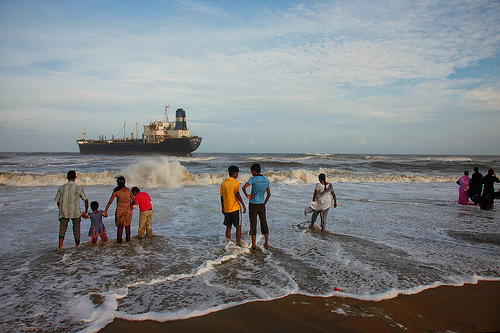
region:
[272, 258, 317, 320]
edge of a shore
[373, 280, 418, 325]
part of a shore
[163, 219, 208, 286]
part of a water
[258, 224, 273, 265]
part of a leg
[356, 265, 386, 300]
edge of a shore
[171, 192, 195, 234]
part fo a water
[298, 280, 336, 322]
edge of a shore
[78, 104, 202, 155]
a ship near the coast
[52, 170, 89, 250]
a person on the beach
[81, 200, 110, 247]
a child on the beach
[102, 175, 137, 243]
a person on the beach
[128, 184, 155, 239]
a person wearing red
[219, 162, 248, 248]
a person wearing a yellow shirt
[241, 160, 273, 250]
a person wearing a blue shirt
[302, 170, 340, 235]
a person standing in the water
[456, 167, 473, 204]
a person standing in the water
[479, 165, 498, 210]
a person standing in the water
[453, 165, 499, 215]
The people are standing in water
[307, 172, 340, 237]
The woman is wearing a white shirt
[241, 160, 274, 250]
The guy is wearing a blue shirt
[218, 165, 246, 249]
The person is wearing a yellow shirt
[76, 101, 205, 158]
A large ship is in the ocean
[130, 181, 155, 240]
The child is looking down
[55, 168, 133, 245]
The adults are holding the childs arms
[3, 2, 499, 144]
Cloud covered sky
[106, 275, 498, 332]
The sand on the beach is wet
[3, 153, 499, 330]
The ocean is wavy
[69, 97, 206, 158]
A tanker on the surf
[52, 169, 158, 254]
A family watching the tanker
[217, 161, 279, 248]
Two friends watching the tanker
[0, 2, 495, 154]
A very overcast sky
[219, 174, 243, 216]
An orange shirt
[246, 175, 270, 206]
A blue shirt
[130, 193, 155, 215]
A red shirt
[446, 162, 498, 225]
A group of friends standing in the surf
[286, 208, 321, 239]
A fishing net in the surf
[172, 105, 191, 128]
Smokestacks on the ship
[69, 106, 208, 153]
ship in the ocean near shore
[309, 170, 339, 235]
woman standing in the water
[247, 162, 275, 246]
boy standing in the water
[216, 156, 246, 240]
boy standing in the water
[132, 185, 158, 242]
boy standing in the water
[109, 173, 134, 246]
woman standing in the water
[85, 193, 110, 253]
child standing in the water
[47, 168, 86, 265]
man standing in the water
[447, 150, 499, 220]
three people standing in the water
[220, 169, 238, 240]
boy wearing yellow shirt